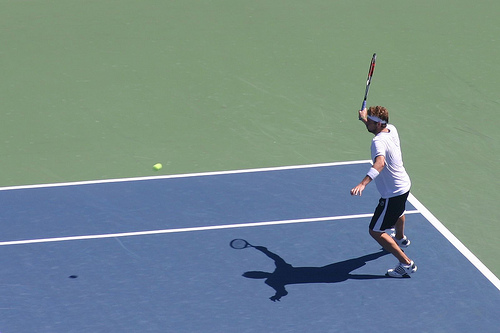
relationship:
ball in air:
[152, 161, 164, 174] [4, 3, 498, 240]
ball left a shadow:
[152, 161, 164, 174] [69, 273, 80, 280]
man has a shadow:
[351, 105, 419, 279] [231, 237, 412, 302]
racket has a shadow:
[359, 53, 377, 119] [231, 237, 254, 250]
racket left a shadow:
[359, 53, 377, 119] [231, 237, 254, 250]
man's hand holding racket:
[359, 107, 370, 123] [359, 53, 377, 119]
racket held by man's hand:
[359, 53, 377, 119] [359, 107, 370, 123]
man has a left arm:
[351, 105, 419, 279] [361, 140, 387, 186]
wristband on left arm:
[366, 165, 381, 181] [361, 140, 387, 186]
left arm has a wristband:
[361, 140, 387, 186] [366, 165, 381, 181]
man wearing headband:
[351, 105, 419, 279] [365, 113, 388, 126]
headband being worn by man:
[365, 113, 388, 126] [351, 105, 419, 279]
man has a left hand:
[351, 105, 419, 279] [350, 182, 367, 198]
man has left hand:
[351, 105, 419, 279] [350, 182, 367, 198]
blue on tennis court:
[2, 163, 498, 331] [2, 163, 498, 331]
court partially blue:
[4, 3, 495, 332] [2, 163, 498, 331]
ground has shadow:
[2, 2, 500, 331] [231, 237, 412, 302]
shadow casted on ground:
[231, 237, 412, 302] [2, 2, 500, 331]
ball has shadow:
[152, 161, 164, 174] [69, 273, 80, 280]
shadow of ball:
[69, 273, 80, 280] [152, 161, 164, 174]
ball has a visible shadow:
[152, 161, 164, 174] [69, 273, 80, 280]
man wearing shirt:
[351, 105, 419, 279] [370, 123, 413, 198]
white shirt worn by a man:
[370, 123, 413, 198] [351, 105, 419, 279]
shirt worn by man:
[370, 123, 413, 198] [351, 105, 419, 279]